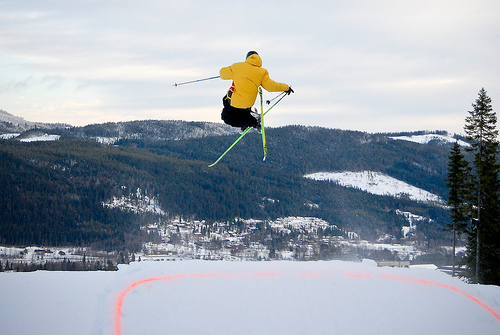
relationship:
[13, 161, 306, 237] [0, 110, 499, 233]
pines on mountain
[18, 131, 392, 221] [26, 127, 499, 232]
forest on mountain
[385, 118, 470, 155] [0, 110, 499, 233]
snowcap on mountain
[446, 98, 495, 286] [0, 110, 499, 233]
trees on mountain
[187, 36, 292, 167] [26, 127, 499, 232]
person in mountain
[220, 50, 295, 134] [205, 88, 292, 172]
person wears skis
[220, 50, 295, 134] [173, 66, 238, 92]
person holds pole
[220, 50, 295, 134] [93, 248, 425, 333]
person on snow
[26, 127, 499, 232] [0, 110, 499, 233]
mountain has mountain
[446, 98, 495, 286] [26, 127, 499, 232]
trees on mountain